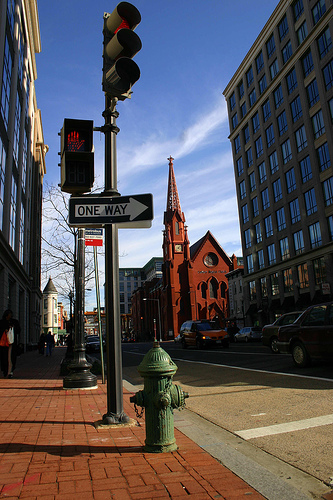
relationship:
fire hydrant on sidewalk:
[127, 340, 189, 456] [4, 345, 270, 500]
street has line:
[93, 340, 332, 489] [122, 342, 331, 444]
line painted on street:
[122, 342, 331, 444] [93, 340, 332, 489]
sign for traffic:
[67, 195, 153, 230] [178, 303, 331, 368]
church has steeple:
[133, 156, 243, 342] [164, 156, 190, 340]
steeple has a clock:
[164, 156, 190, 340] [173, 245, 183, 255]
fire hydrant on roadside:
[127, 340, 189, 456] [73, 343, 289, 499]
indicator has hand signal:
[57, 119, 96, 194] [65, 127, 87, 152]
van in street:
[179, 319, 231, 350] [93, 340, 332, 489]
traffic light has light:
[99, 1, 143, 427] [104, 1, 140, 36]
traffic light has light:
[99, 1, 143, 427] [102, 29, 142, 60]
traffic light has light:
[99, 1, 143, 427] [103, 56, 142, 90]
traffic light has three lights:
[99, 1, 143, 427] [102, 2, 141, 101]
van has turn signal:
[179, 319, 231, 350] [202, 336, 207, 340]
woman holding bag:
[0, 319, 13, 380] [8, 327, 15, 345]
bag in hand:
[8, 327, 15, 345] [6, 340, 10, 346]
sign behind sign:
[83, 224, 106, 384] [67, 195, 153, 230]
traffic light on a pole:
[99, 1, 143, 427] [103, 95, 135, 432]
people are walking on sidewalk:
[36, 332, 57, 356] [4, 345, 270, 500]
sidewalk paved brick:
[4, 345, 270, 500] [63, 430, 86, 442]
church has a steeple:
[133, 156, 243, 342] [164, 156, 190, 340]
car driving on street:
[278, 303, 332, 366] [93, 340, 332, 489]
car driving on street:
[262, 312, 301, 357] [93, 340, 332, 489]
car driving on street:
[179, 319, 231, 350] [93, 340, 332, 489]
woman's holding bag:
[0, 310, 22, 379] [8, 327, 15, 345]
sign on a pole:
[67, 195, 153, 230] [103, 95, 132, 425]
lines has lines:
[93, 340, 332, 489] [122, 342, 331, 444]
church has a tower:
[133, 156, 243, 342] [164, 156, 190, 340]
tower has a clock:
[164, 156, 190, 340] [163, 245, 171, 255]